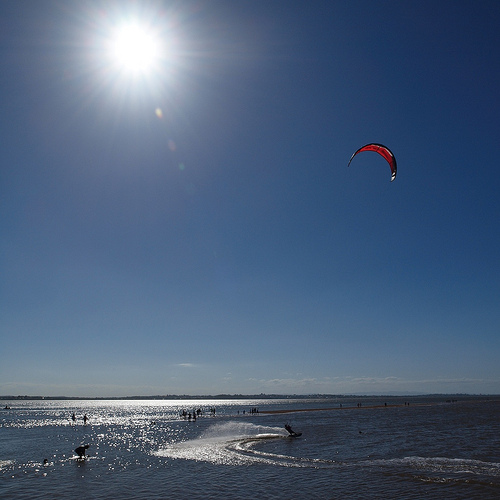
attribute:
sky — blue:
[11, 23, 391, 379]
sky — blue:
[240, 21, 482, 102]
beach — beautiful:
[8, 347, 490, 499]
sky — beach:
[59, 88, 192, 180]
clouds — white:
[135, 134, 307, 244]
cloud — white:
[167, 354, 429, 393]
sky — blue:
[50, 158, 286, 313]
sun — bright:
[67, 7, 196, 112]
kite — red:
[336, 138, 406, 184]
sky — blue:
[0, 0, 497, 312]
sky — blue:
[92, 229, 406, 324]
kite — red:
[344, 142, 399, 179]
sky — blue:
[0, 6, 497, 392]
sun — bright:
[73, 5, 191, 99]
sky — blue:
[98, 183, 338, 307]